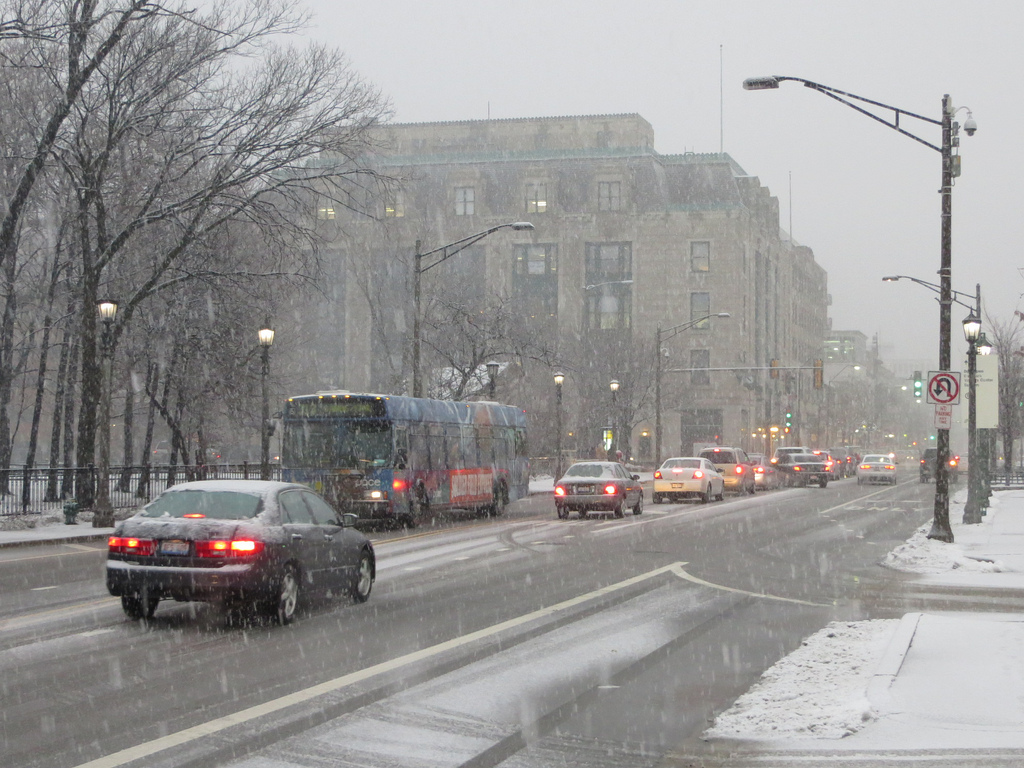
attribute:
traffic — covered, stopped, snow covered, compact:
[95, 471, 386, 624]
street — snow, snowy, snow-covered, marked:
[3, 454, 974, 767]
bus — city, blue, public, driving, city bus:
[272, 378, 541, 535]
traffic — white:
[646, 452, 726, 509]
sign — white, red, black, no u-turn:
[921, 364, 967, 410]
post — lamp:
[924, 93, 974, 547]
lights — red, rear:
[102, 530, 155, 564]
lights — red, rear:
[206, 535, 263, 564]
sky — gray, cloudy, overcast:
[2, 3, 1024, 391]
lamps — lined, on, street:
[736, 66, 786, 97]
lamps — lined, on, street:
[509, 219, 535, 240]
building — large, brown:
[225, 95, 837, 489]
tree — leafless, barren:
[2, 2, 430, 519]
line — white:
[74, 554, 690, 767]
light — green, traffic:
[911, 369, 924, 391]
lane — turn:
[764, 471, 953, 529]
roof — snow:
[330, 107, 653, 124]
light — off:
[712, 305, 733, 322]